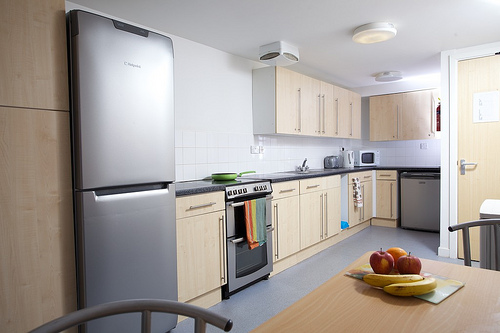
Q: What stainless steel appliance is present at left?
A: Stacked refrigerator.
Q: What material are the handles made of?
A: Metal.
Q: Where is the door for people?
A: At right.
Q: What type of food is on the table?
A: Fruit.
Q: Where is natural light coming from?
A: Out of frame to the right.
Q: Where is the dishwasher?
A: In the far corner.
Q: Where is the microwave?
A: In the far corner.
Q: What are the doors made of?
A: Wood.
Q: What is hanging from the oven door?
A: A multicolored towel.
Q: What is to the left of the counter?
A: A stainless steel refrigerator.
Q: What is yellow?
A: Bananas.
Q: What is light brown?
A: Cabinets.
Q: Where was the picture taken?
A: In a kitchen.